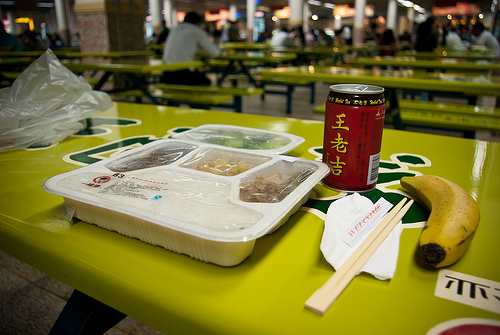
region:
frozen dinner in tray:
[43, 137, 333, 269]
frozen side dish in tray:
[173, 121, 305, 156]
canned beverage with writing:
[321, 82, 384, 190]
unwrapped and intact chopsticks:
[302, 196, 417, 314]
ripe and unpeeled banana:
[399, 174, 480, 269]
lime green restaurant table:
[3, 100, 499, 334]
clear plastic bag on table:
[2, 47, 115, 154]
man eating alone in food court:
[160, 9, 220, 85]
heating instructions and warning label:
[80, 168, 170, 204]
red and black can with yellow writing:
[321, 81, 388, 193]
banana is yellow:
[408, 170, 471, 280]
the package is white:
[131, 140, 319, 245]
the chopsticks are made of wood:
[319, 222, 363, 307]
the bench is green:
[436, 139, 495, 167]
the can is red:
[326, 104, 384, 182]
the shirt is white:
[169, 25, 214, 66]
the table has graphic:
[84, 115, 146, 145]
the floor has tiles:
[16, 277, 43, 329]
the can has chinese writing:
[328, 120, 350, 171]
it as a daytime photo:
[4, 5, 495, 327]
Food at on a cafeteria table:
[7, 9, 482, 319]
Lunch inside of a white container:
[48, 52, 484, 312]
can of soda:
[307, 54, 397, 196]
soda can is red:
[318, 67, 388, 192]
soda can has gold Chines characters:
[317, 62, 393, 195]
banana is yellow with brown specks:
[391, 157, 481, 274]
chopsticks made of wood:
[274, 189, 424, 330]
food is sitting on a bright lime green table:
[17, 52, 498, 307]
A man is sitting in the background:
[87, 3, 497, 333]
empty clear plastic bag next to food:
[8, 41, 113, 188]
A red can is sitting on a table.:
[316, 72, 387, 197]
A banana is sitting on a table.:
[385, 161, 485, 271]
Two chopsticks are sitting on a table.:
[297, 190, 413, 320]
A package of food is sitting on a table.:
[40, 135, 330, 271]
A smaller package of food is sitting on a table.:
[160, 120, 305, 160]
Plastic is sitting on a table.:
[0, 40, 120, 155]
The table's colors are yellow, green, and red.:
[0, 95, 496, 331]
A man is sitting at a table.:
[155, 5, 232, 95]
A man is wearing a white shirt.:
[150, 5, 222, 70]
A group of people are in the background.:
[148, 0, 498, 61]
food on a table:
[147, 91, 446, 257]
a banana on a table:
[380, 141, 450, 278]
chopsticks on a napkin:
[323, 182, 429, 316]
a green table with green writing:
[89, 87, 177, 165]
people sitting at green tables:
[135, 32, 470, 112]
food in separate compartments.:
[140, 145, 246, 240]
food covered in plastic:
[85, 70, 280, 267]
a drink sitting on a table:
[295, 77, 405, 205]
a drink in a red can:
[306, 63, 394, 146]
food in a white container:
[72, 80, 262, 286]